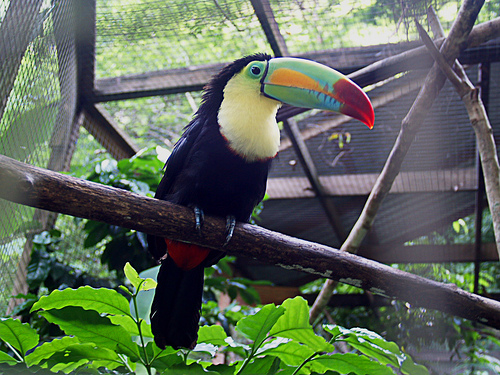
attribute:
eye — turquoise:
[240, 54, 269, 78]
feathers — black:
[145, 254, 215, 348]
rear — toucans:
[123, 207, 235, 274]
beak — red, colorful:
[267, 57, 372, 127]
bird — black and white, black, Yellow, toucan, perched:
[124, 52, 384, 362]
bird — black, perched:
[147, 51, 372, 348]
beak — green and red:
[268, 59, 380, 130]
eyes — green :
[244, 41, 285, 114]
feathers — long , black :
[147, 153, 244, 352]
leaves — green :
[242, 291, 284, 320]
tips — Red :
[121, 210, 175, 330]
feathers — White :
[192, 50, 312, 198]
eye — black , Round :
[225, 41, 272, 91]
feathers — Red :
[147, 211, 218, 290]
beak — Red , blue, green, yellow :
[265, 54, 376, 156]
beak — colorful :
[246, 24, 433, 203]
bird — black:
[131, 47, 371, 366]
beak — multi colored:
[249, 51, 382, 141]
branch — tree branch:
[45, 162, 448, 322]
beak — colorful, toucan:
[260, 50, 379, 133]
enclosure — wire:
[9, 3, 186, 107]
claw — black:
[190, 207, 207, 241]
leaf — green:
[33, 285, 135, 320]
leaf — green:
[26, 337, 125, 366]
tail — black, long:
[147, 257, 216, 351]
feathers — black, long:
[179, 307, 204, 347]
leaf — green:
[30, 280, 131, 316]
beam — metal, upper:
[70, 24, 117, 118]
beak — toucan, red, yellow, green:
[259, 47, 384, 128]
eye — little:
[242, 57, 263, 79]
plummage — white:
[220, 96, 285, 158]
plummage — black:
[193, 157, 263, 207]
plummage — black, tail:
[152, 255, 202, 348]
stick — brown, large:
[411, 45, 499, 248]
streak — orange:
[266, 60, 328, 99]